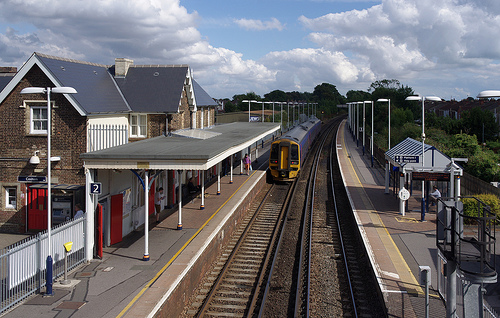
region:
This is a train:
[265, 96, 335, 181]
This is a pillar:
[142, 167, 152, 261]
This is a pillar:
[174, 167, 185, 236]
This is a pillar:
[198, 166, 205, 213]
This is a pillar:
[215, 158, 222, 195]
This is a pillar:
[385, 95, 392, 157]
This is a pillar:
[368, 100, 377, 167]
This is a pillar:
[358, 100, 365, 155]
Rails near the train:
[190, 115, 365, 317]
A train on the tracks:
[270, 117, 323, 181]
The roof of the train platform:
[83, 121, 279, 170]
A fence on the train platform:
[0, 215, 85, 307]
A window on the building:
[29, 105, 49, 130]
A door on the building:
[27, 187, 47, 232]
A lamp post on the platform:
[406, 94, 443, 196]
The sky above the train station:
[0, 2, 497, 99]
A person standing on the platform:
[153, 187, 166, 221]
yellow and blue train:
[261, 119, 334, 201]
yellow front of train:
[263, 143, 301, 182]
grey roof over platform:
[101, 106, 281, 196]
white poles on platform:
[125, 154, 242, 272]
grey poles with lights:
[315, 97, 494, 279]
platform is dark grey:
[62, 225, 187, 308]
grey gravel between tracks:
[234, 207, 341, 305]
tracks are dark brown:
[212, 174, 299, 316]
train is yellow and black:
[265, 135, 306, 181]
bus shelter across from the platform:
[377, 129, 480, 249]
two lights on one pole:
[15, 76, 92, 315]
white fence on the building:
[78, 110, 132, 160]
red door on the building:
[19, 184, 63, 240]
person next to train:
[237, 153, 265, 179]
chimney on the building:
[109, 52, 147, 88]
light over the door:
[24, 142, 53, 175]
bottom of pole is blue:
[33, 247, 75, 299]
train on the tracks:
[263, 101, 333, 193]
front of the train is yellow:
[264, 132, 305, 189]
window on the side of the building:
[18, 97, 61, 139]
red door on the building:
[25, 187, 54, 231]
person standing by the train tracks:
[239, 150, 256, 172]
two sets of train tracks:
[171, 103, 378, 317]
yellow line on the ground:
[107, 158, 274, 317]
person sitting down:
[423, 185, 449, 211]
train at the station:
[1, 25, 498, 317]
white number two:
[86, 182, 106, 194]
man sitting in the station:
[418, 183, 445, 211]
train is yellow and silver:
[270, 135, 302, 182]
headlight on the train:
[272, 161, 300, 171]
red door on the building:
[91, 191, 129, 247]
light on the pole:
[18, 82, 77, 98]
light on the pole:
[403, 90, 442, 103]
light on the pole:
[376, 93, 388, 105]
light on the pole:
[243, 96, 256, 105]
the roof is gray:
[82, 118, 280, 155]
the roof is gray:
[38, 53, 128, 113]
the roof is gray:
[110, 64, 187, 110]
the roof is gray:
[190, 74, 217, 105]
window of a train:
[271, 143, 279, 160]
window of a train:
[288, 146, 298, 162]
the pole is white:
[142, 166, 150, 257]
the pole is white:
[175, 170, 181, 222]